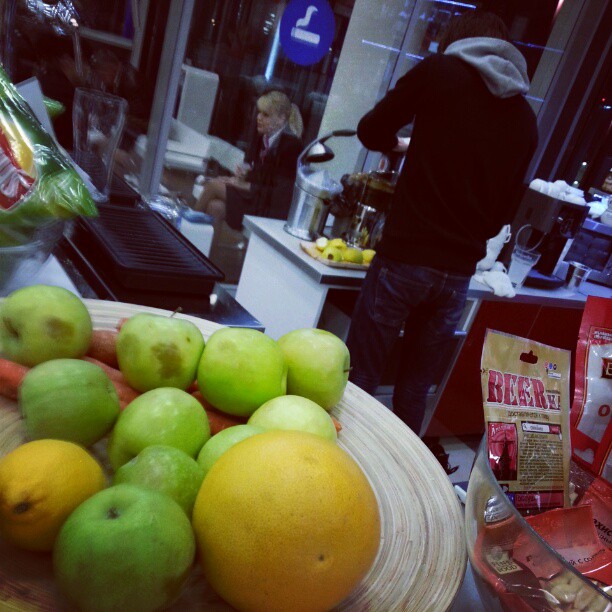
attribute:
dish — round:
[3, 285, 479, 608]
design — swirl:
[356, 420, 466, 585]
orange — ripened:
[184, 426, 388, 608]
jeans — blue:
[347, 233, 482, 438]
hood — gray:
[431, 24, 542, 108]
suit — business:
[230, 132, 297, 207]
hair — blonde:
[251, 86, 305, 132]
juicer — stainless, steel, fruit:
[277, 122, 353, 252]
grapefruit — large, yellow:
[179, 423, 392, 609]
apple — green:
[2, 280, 99, 366]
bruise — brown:
[39, 311, 80, 346]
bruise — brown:
[150, 340, 187, 380]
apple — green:
[105, 301, 207, 392]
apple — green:
[47, 490, 198, 606]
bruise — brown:
[147, 544, 199, 605]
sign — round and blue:
[294, 65, 336, 78]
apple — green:
[296, 334, 342, 398]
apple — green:
[127, 403, 188, 456]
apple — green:
[138, 444, 164, 541]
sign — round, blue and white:
[290, 61, 320, 71]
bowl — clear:
[6, 170, 90, 267]